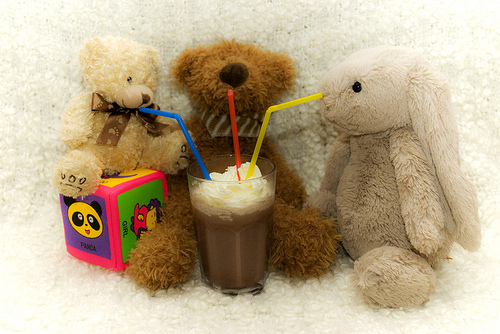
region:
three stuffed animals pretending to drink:
[45, 27, 489, 321]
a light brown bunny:
[305, 49, 491, 316]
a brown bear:
[127, 30, 341, 295]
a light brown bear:
[45, 27, 196, 207]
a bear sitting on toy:
[49, 27, 197, 276]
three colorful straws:
[127, 77, 334, 187]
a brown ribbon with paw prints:
[87, 85, 169, 150]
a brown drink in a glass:
[180, 142, 282, 301]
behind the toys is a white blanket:
[3, 0, 498, 332]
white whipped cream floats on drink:
[181, 156, 282, 296]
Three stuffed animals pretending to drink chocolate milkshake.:
[52, 28, 489, 318]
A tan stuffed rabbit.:
[311, 47, 490, 317]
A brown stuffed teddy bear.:
[135, 43, 337, 307]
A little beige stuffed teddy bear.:
[49, 41, 192, 204]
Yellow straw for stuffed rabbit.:
[243, 93, 326, 187]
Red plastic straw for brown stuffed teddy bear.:
[220, 83, 245, 178]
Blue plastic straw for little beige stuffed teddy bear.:
[138, 101, 213, 195]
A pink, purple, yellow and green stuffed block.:
[53, 159, 167, 277]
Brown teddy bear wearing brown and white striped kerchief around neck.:
[195, 105, 266, 141]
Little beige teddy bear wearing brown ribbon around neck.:
[85, 91, 171, 157]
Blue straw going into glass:
[137, 91, 237, 208]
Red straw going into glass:
[217, 92, 253, 159]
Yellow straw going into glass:
[255, 98, 307, 193]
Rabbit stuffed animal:
[324, 42, 451, 253]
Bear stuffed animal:
[186, 38, 307, 287]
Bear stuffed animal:
[50, 39, 149, 191]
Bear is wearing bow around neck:
[71, 67, 227, 175]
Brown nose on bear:
[213, 43, 253, 112]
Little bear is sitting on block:
[51, 67, 154, 278]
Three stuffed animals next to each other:
[67, 16, 487, 252]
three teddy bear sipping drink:
[50, 18, 460, 311]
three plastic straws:
[130, 76, 322, 186]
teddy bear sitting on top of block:
[55, 27, 172, 294]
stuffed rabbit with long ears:
[317, 32, 463, 292]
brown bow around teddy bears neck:
[77, 81, 167, 161]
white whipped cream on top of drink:
[168, 143, 288, 218]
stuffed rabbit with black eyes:
[302, 28, 467, 296]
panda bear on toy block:
[65, 181, 120, 256]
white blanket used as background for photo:
[148, 3, 359, 58]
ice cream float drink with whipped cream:
[136, 69, 333, 301]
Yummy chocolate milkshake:
[190, 166, 280, 269]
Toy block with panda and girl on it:
[61, 181, 154, 253]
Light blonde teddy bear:
[87, 45, 157, 130]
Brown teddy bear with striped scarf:
[197, 46, 282, 132]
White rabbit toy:
[315, 63, 420, 181]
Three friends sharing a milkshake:
[176, 91, 308, 191]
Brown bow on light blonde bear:
[95, 96, 130, 136]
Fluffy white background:
[15, 20, 51, 86]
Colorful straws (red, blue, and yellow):
[185, 100, 280, 197]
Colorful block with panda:
[61, 198, 113, 255]